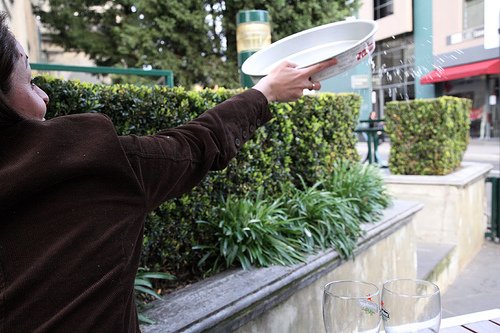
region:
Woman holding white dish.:
[231, 16, 383, 128]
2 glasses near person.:
[339, 268, 421, 327]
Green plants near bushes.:
[188, 184, 403, 272]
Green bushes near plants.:
[125, 51, 266, 176]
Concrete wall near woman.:
[170, 232, 432, 296]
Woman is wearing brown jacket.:
[82, 172, 146, 299]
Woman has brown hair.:
[6, 40, 63, 182]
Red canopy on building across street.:
[410, 55, 495, 83]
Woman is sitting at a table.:
[158, 275, 330, 318]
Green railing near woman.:
[49, 41, 232, 102]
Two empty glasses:
[316, 265, 446, 330]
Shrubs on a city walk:
[383, 102, 476, 183]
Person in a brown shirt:
[0, 22, 287, 328]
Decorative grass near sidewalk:
[196, 188, 411, 274]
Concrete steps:
[406, 225, 467, 305]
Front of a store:
[426, 62, 496, 112]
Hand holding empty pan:
[235, 21, 411, 94]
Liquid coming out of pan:
[358, 27, 449, 83]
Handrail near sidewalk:
[35, 45, 185, 96]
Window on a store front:
[369, 6, 422, 50]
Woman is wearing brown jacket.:
[41, 137, 128, 313]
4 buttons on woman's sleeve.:
[214, 117, 264, 143]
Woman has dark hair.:
[6, 61, 59, 181]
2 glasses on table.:
[322, 256, 420, 309]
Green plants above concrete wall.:
[218, 176, 394, 268]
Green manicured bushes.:
[93, 57, 345, 228]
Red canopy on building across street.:
[431, 50, 498, 110]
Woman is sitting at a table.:
[113, 274, 474, 331]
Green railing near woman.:
[67, 37, 176, 134]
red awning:
[417, 59, 497, 86]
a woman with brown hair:
[0, 6, 50, 134]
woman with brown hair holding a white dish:
[0, 17, 384, 331]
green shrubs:
[382, 95, 472, 175]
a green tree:
[114, 27, 211, 64]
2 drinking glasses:
[321, 276, 441, 328]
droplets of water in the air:
[365, 20, 463, 106]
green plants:
[208, 190, 354, 266]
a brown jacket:
[0, 80, 272, 330]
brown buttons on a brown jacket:
[1, 87, 276, 331]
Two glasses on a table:
[316, 275, 497, 332]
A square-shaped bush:
[386, 93, 479, 172]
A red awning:
[415, 57, 497, 91]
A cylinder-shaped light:
[231, 5, 273, 52]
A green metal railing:
[43, 52, 181, 89]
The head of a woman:
[0, 22, 54, 123]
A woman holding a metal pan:
[0, 9, 379, 331]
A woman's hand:
[254, 56, 331, 103]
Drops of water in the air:
[369, 28, 464, 93]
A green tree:
[30, 1, 234, 84]